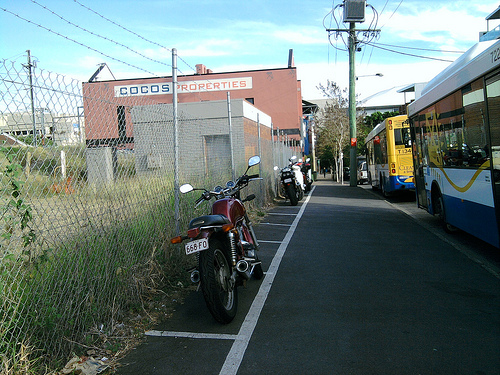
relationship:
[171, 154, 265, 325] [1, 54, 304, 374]
motorcycle by fence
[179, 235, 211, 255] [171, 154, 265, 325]
license plate on motorcycle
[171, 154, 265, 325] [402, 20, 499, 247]
motorcycle near bus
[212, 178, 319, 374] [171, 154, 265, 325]
white line next to motorcycle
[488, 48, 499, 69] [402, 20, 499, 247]
722 on bus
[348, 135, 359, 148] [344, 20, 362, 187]
sign on pole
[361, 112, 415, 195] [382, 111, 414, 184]
bus has back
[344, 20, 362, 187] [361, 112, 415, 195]
pole by bus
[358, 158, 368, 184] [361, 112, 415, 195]
minivan in front of bus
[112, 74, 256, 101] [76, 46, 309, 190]
sign on building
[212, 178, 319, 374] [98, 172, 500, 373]
white line on sidewalk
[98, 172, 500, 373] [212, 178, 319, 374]
sidewalk with white line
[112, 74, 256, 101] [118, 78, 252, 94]
sign says cocos properties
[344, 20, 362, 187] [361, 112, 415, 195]
pole next to bus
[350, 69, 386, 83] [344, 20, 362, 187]
streetlight near pole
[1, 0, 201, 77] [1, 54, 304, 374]
barbed wire over fence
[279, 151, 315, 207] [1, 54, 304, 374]
motorcycles parked by fence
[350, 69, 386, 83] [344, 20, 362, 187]
streetlight on pole